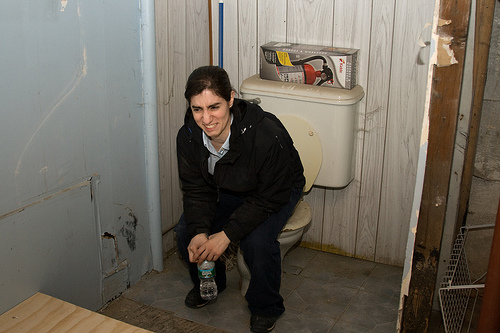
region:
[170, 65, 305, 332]
woman sitting on a toilet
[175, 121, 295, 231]
black jacket of woman on a toilet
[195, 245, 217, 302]
water bottle woman is holding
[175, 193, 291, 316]
blue jeans the woman is wearing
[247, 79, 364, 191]
tank of the toilet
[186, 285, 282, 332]
black shoes woman is earing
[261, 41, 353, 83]
fire extinguisher box on the toilet tank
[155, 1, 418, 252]
wood paneling behind the toilet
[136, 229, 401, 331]
cement floor around the toilet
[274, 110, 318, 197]
lifted lid of the toilet bowl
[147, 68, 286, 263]
this is a lady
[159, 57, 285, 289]
the lady is using the toilet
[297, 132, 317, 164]
this is the lid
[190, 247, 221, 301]
she is carrying a bottle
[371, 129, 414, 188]
this is the wall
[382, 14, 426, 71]
the wall is wooden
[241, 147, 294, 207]
this is the jacket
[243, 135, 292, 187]
it is black in color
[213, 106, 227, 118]
she is light skinned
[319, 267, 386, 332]
this is the floor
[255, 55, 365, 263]
This is a toilet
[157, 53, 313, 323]
The woman is on the toilet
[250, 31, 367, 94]
A fire extinguisher box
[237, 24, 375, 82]
The box is on top of the toilet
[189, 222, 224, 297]
The woman is holding a water bottle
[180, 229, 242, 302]
The water bottle is both of her hands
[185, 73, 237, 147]
The woman is making a disgruntled face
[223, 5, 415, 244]
Wood panels behind the toilet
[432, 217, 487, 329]
A wire tray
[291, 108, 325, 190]
The toilet lid is open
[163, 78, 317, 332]
the woman is sitted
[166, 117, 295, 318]
the clothes are black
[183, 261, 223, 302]
the water bottle is clear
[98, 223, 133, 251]
crack is on the wall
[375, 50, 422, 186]
the wall is wooden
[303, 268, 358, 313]
the floor is grey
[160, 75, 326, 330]
the woman is taking a dump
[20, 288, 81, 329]
the table is wooden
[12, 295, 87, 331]
the table is brown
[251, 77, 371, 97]
the lid is dusty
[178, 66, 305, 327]
woman sitting on toilet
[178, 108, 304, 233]
black jacket of woman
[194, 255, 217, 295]
bottle of water in hand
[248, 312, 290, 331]
black shoe of woman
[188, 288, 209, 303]
black shoe of woman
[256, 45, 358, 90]
grey box on toilet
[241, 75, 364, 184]
white tank of toilet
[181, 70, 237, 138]
face of woman in room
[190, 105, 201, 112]
eye of woman in room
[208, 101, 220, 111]
eye of woman in room